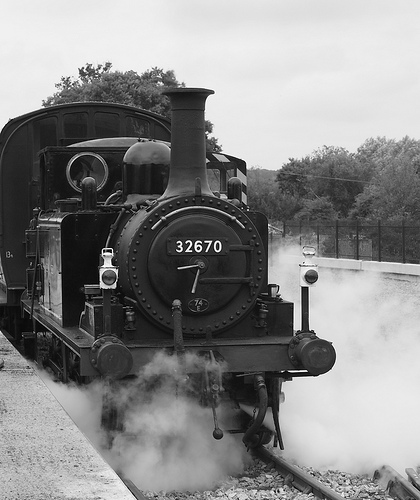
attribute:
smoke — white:
[249, 226, 417, 356]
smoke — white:
[341, 276, 405, 436]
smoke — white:
[129, 389, 201, 483]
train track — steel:
[119, 428, 363, 499]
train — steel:
[9, 70, 370, 469]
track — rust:
[201, 429, 419, 495]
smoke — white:
[88, 228, 413, 489]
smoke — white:
[2, 236, 419, 498]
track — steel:
[157, 430, 419, 497]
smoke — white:
[33, 347, 249, 497]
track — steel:
[113, 441, 349, 498]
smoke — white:
[29, 228, 419, 492]